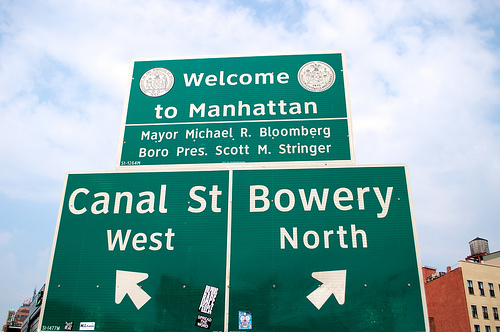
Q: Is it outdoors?
A: Yes, it is outdoors.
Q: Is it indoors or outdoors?
A: It is outdoors.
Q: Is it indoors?
A: No, it is outdoors.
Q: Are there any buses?
A: No, there are no buses.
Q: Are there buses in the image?
A: No, there are no buses.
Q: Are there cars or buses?
A: No, there are no buses or cars.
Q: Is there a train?
A: Yes, there is a train.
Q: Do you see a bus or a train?
A: Yes, there is a train.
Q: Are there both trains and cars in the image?
A: No, there is a train but no cars.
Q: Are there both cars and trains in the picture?
A: No, there is a train but no cars.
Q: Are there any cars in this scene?
A: No, there are no cars.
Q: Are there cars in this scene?
A: No, there are no cars.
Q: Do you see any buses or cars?
A: No, there are no cars or buses.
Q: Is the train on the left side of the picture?
A: Yes, the train is on the left of the image.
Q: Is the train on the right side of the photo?
A: No, the train is on the left of the image.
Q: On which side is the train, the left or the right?
A: The train is on the left of the image.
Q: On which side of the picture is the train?
A: The train is on the left of the image.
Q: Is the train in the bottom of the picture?
A: Yes, the train is in the bottom of the image.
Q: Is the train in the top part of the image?
A: No, the train is in the bottom of the image.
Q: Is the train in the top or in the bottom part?
A: The train is in the bottom of the image.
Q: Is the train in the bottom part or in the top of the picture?
A: The train is in the bottom of the image.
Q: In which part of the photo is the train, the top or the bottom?
A: The train is in the bottom of the image.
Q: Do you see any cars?
A: No, there are no cars.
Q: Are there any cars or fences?
A: No, there are no cars or fences.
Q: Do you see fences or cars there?
A: No, there are no cars or fences.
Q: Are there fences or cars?
A: No, there are no cars or fences.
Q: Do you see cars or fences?
A: No, there are no cars or fences.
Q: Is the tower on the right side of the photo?
A: Yes, the tower is on the right of the image.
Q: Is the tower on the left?
A: No, the tower is on the right of the image.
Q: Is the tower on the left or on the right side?
A: The tower is on the right of the image.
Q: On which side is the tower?
A: The tower is on the right of the image.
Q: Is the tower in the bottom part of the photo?
A: Yes, the tower is in the bottom of the image.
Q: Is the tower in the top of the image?
A: No, the tower is in the bottom of the image.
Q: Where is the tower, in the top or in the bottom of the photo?
A: The tower is in the bottom of the image.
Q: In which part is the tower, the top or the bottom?
A: The tower is in the bottom of the image.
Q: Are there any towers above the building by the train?
A: Yes, there is a tower above the building.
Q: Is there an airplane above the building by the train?
A: No, there is a tower above the building.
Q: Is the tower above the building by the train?
A: Yes, the tower is above the building.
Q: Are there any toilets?
A: No, there are no toilets.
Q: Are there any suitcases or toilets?
A: No, there are no toilets or suitcases.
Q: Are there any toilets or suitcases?
A: No, there are no toilets or suitcases.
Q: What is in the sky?
A: The clouds are in the sky.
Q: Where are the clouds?
A: The clouds are in the sky.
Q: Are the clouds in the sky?
A: Yes, the clouds are in the sky.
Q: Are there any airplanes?
A: No, there are no airplanes.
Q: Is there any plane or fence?
A: No, there are no airplanes or fences.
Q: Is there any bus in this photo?
A: No, there are no buses.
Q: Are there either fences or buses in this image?
A: No, there are no buses or fences.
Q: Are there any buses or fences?
A: No, there are no buses or fences.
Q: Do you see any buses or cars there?
A: No, there are no buses or cars.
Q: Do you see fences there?
A: No, there are no fences.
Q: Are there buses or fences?
A: No, there are no fences or buses.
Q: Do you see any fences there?
A: No, there are no fences.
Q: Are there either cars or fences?
A: No, there are no fences or cars.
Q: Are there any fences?
A: No, there are no fences.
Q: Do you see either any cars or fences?
A: No, there are no fences or cars.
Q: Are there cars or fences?
A: No, there are no fences or cars.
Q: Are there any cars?
A: No, there are no cars.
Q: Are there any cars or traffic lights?
A: No, there are no cars or traffic lights.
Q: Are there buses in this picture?
A: No, there are no buses.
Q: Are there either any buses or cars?
A: No, there are no buses or cars.